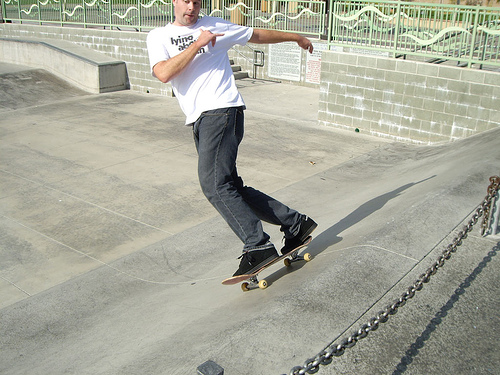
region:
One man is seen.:
[135, 13, 345, 299]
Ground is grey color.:
[42, 225, 153, 340]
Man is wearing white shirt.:
[198, 67, 233, 98]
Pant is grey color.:
[195, 135, 250, 225]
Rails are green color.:
[322, 11, 459, 46]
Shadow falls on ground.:
[335, 175, 415, 236]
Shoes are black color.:
[227, 223, 317, 293]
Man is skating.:
[165, 22, 318, 300]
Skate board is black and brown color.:
[207, 237, 312, 308]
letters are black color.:
[163, 28, 208, 66]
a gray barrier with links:
[296, 322, 410, 369]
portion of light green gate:
[343, 6, 457, 45]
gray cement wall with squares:
[341, 60, 412, 127]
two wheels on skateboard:
[240, 277, 267, 298]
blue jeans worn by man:
[192, 116, 240, 244]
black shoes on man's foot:
[230, 246, 277, 273]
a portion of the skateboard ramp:
[335, 151, 457, 221]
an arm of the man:
[254, 25, 317, 50]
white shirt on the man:
[146, 35, 248, 109]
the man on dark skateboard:
[151, 0, 330, 290]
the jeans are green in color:
[182, 119, 301, 242]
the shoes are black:
[222, 236, 304, 283]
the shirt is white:
[141, 21, 262, 115]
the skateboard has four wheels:
[221, 233, 349, 295]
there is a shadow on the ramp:
[335, 165, 409, 243]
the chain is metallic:
[391, 208, 478, 327]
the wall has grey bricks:
[363, 76, 456, 139]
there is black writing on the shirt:
[172, 31, 232, 68]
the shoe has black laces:
[226, 248, 270, 270]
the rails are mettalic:
[366, 6, 477, 57]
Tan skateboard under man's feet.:
[221, 234, 322, 292]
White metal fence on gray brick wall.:
[2, 0, 499, 74]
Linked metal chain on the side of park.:
[290, 173, 499, 373]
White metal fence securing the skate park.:
[0, 1, 497, 69]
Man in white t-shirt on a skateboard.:
[145, 1, 320, 292]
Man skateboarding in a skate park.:
[145, 0, 330, 292]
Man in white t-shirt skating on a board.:
[145, 1, 338, 291]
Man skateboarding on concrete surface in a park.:
[2, 1, 496, 373]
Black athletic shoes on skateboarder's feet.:
[231, 216, 317, 276]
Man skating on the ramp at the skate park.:
[105, 0, 420, 356]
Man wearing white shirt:
[160, 7, 237, 67]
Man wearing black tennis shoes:
[226, 228, 326, 269]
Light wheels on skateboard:
[251, 267, 285, 317]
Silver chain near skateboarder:
[343, 209, 442, 332]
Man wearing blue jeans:
[185, 125, 290, 241]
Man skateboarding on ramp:
[136, 96, 363, 356]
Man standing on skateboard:
[230, 216, 314, 306]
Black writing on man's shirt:
[176, 7, 207, 79]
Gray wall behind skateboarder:
[343, 61, 423, 177]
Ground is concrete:
[21, 117, 346, 309]